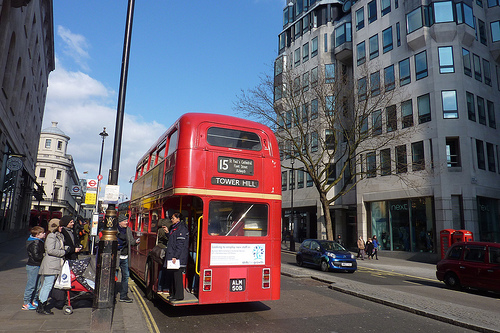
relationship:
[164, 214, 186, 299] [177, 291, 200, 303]
woman standing on bus platform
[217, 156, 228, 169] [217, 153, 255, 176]
number on display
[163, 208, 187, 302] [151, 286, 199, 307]
bus operator on stair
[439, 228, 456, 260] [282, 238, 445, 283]
telephone booth on sidewalk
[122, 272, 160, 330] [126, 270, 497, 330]
line on ground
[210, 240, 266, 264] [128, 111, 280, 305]
sign in front of bus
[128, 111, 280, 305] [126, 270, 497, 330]
bus on street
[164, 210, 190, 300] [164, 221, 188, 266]
man in jacket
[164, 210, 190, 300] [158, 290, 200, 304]
man standing on bus platform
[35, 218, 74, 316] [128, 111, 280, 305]
woman waiting for bus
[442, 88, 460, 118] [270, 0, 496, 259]
window on building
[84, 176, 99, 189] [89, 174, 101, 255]
sign mounted on pole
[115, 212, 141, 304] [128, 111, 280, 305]
man standing next to bus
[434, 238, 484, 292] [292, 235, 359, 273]
car driving in front of car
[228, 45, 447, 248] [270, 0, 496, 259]
tree standing in front of building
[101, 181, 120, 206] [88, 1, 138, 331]
sign mounted on post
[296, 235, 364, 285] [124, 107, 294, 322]
car passing bus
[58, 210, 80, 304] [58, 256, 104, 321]
woman pushing stroller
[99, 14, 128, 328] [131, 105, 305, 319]
post by bus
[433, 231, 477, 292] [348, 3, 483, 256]
telephone booth by building